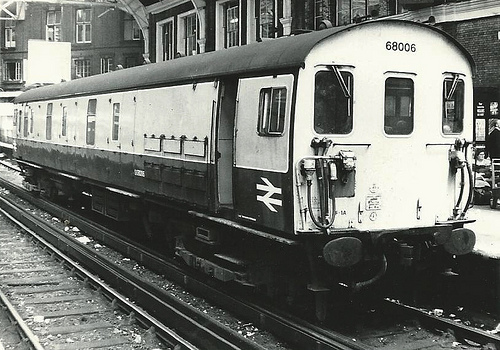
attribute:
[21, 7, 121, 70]
brick building — old , brick 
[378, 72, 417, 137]
window — small 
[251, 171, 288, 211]
pattern — white 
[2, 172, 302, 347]
tracks — empty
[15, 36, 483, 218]
train — white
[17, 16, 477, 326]
car — lone, black and white, passenger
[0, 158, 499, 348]
railway — dirty , littered 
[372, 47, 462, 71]
number — black 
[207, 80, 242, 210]
door — open 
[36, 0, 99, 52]
windows — white 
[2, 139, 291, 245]
strip — dark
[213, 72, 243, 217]
door — open